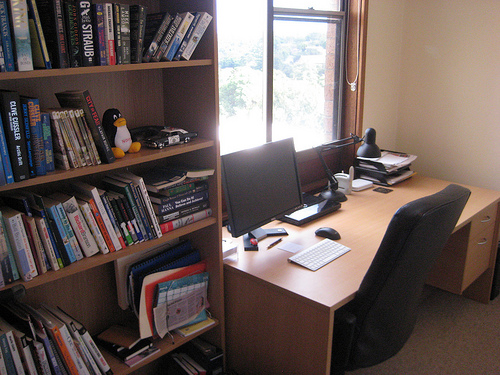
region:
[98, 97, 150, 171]
a pinguin plushie on a shelf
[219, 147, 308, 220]
a black computer monitor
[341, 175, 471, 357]
a black swiveling chair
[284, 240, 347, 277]
a white keyboard on a wooden desk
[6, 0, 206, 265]
a bookshelf with many books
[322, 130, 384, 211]
a black desk lamp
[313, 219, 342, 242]
a black wireless mouse on a desk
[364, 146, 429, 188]
a stack of papers on a desk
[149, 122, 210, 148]
a toy police car on a shelf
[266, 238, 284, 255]
a pen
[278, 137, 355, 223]
a black lamp on table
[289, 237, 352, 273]
a white keyboard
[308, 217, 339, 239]
a black mouse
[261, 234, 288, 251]
a pencil on desk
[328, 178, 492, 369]
a black office chair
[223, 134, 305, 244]
a tv monitor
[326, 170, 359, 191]
a white pencil holder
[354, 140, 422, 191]
a paper organizer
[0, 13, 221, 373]
a bookshelf full of books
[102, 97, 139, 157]
a penguin stuff animal on bookshelf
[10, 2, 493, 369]
an office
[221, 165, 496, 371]
a large brown desk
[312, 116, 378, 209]
table lamp on desk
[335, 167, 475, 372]
dark office chair beside desk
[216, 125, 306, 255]
large computer monitor on desk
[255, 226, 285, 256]
pen on desk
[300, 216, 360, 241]
black cordless computer mouse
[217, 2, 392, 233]
window in front of desk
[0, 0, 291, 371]
bookcase next to desk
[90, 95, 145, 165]
plush penguin on shelf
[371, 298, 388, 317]
THE CHAIR IS BLACK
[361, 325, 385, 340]
THE CHAIR IS BLACK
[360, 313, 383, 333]
THE CHAIR IS BLACK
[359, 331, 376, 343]
THE CHAIR IS BLACK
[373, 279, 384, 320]
THE CHAIR IS BLACK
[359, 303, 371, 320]
THE CHAIR IS BLACK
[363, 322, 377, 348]
THE CHAIR IS BLACK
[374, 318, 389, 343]
THE CHAIR IS BLACK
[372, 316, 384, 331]
THE CHAIR IS BLACK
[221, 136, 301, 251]
Computer monitor on the desk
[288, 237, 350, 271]
Key board on the desk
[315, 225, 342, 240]
Mouse on the desk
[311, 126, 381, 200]
Light on the desk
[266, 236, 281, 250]
Pen on the desk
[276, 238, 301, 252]
Paper on the desk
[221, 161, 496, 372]
Brown chair under the window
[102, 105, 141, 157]
penguin on the shelf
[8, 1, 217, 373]
Books on the chair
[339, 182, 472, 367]
Computer chair under the desk